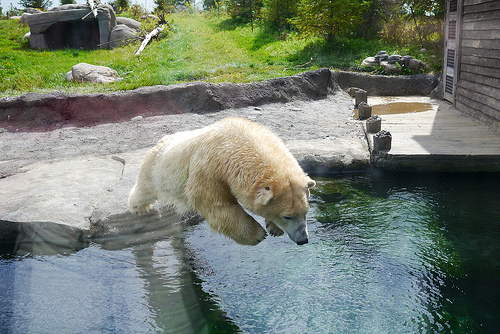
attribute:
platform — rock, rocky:
[2, 70, 374, 221]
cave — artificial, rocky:
[18, 2, 148, 54]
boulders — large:
[15, 7, 161, 86]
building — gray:
[443, 3, 499, 143]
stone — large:
[67, 61, 122, 86]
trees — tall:
[204, 1, 449, 47]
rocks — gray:
[366, 57, 377, 70]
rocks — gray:
[376, 53, 386, 69]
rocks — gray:
[383, 56, 396, 73]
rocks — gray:
[398, 55, 410, 73]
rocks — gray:
[411, 59, 422, 74]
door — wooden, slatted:
[437, 2, 469, 129]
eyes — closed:
[259, 204, 329, 231]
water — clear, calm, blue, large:
[0, 170, 498, 332]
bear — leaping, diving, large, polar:
[126, 117, 316, 247]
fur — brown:
[192, 135, 315, 249]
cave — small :
[29, 10, 113, 56]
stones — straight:
[348, 82, 394, 152]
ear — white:
[303, 177, 315, 190]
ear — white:
[261, 190, 273, 207]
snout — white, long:
[284, 220, 309, 244]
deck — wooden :
[336, 81, 498, 182]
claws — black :
[227, 218, 292, 253]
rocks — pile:
[356, 45, 431, 72]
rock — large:
[60, 61, 126, 86]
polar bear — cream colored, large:
[116, 111, 320, 258]